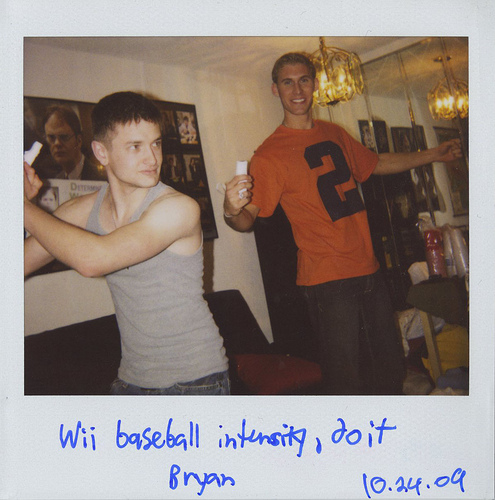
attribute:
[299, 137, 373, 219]
2 — large, black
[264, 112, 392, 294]
t-shirt — red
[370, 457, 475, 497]
date — handwritten, printed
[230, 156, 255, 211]
controller — white, wii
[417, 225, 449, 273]
cups — red, stacks, plastic, clear, white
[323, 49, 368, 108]
lights — bright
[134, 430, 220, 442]
words — handwritten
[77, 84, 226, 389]
man — smiling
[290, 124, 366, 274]
shirt — orange, black, red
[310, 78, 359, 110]
light — reflecting, hanging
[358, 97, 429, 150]
mirror — tall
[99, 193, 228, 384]
tank top — grey, gray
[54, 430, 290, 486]
text — handwritten, blue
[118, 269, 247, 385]
undershirt — grey, gray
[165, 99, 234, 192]
images — framed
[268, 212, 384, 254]
tee shirt — red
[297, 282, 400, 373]
pants — black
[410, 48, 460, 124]
chandler — reflected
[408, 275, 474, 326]
shelf — black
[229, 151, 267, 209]
remote — white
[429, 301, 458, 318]
tablecloth — green